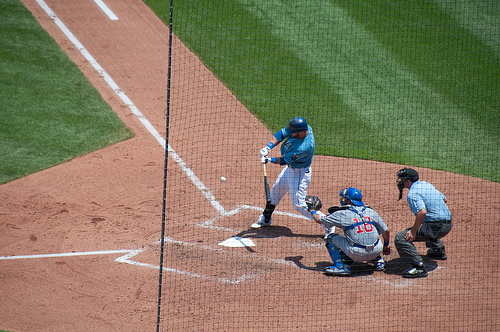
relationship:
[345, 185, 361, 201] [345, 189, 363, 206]
blue helmet on catcher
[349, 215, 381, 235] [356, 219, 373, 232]
red numbers on gray shirt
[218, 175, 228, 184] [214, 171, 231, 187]
baseball in air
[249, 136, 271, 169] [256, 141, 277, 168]
white and blue batting gloves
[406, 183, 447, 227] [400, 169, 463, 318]
blue shirt on umpire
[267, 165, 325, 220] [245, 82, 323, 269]
pair of on batter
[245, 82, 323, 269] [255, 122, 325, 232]
baseball player at bat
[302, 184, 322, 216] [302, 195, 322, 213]
black leather catchers black leather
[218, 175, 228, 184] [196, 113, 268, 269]
baseball in flight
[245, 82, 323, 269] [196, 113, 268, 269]
baseball player swinging at ball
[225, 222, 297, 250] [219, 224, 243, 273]
white home plate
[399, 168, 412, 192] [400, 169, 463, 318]
black face mask on umpire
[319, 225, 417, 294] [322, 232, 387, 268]
pair of grey pair of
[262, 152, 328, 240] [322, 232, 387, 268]
pair of white pair of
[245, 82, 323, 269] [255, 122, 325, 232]
batter swinging bat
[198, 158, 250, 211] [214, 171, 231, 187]
baseball in air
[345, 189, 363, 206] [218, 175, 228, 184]
catcher waiting for baseball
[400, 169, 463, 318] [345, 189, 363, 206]
umpire crouched behind t catcher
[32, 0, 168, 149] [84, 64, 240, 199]
lines down baseline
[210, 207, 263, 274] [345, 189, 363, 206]
home plate in front of catcher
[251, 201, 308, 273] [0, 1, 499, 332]
shadow on field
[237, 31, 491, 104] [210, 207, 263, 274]
net behind home plate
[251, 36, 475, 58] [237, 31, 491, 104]
lines in grass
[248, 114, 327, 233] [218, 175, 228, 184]
batter singing a bat at a baseball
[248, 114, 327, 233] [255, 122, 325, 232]
batter swinging a bat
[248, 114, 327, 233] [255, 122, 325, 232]
batter holding bat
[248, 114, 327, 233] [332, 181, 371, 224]
batter with a mask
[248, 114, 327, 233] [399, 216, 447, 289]
batter with black shoes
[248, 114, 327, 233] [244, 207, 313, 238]
batter with white shoes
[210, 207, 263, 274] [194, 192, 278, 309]
diamon on a baseball base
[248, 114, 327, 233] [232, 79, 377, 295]
batter in blue uniform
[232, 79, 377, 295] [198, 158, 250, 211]
men playing baseball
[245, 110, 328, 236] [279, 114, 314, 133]
batter wearing blue helmet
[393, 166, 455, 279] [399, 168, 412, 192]
umpire wearing black face mask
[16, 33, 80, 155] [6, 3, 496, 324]
green grass in field